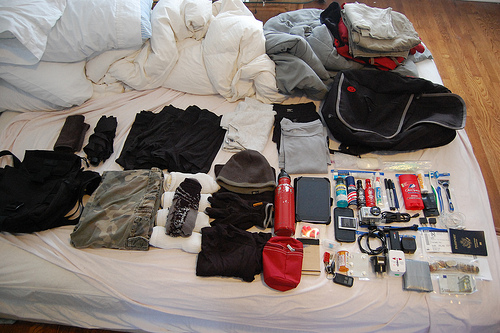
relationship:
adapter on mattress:
[356, 220, 415, 277] [1, 20, 496, 327]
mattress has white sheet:
[1, 20, 496, 327] [4, 75, 497, 328]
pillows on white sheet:
[39, 4, 147, 39] [80, 0, 286, 104]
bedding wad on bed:
[0, 2, 278, 115] [1, 15, 498, 331]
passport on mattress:
[449, 220, 489, 256] [1, 20, 496, 327]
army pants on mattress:
[60, 155, 169, 266] [11, 242, 476, 327]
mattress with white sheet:
[11, 242, 476, 327] [30, 14, 224, 79]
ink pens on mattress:
[28, 28, 458, 318] [4, 45, 490, 325]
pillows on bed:
[3, 0, 153, 102] [14, 15, 434, 309]